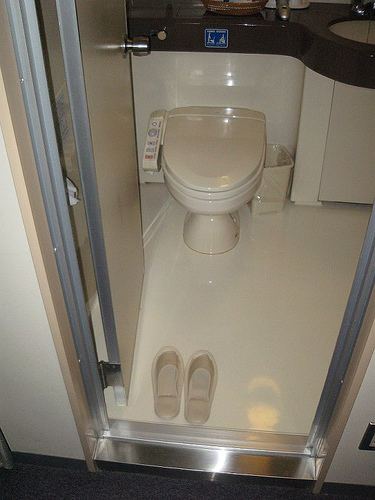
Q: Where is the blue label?
A: Above the toilet.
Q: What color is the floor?
A: Off white.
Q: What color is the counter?
A: Brown.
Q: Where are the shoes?
A: At the front of the door.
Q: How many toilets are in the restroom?
A: 1.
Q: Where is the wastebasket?
A: On the left side of the toilet.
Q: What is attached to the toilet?
A: A panel with controls.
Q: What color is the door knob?
A: Silver.